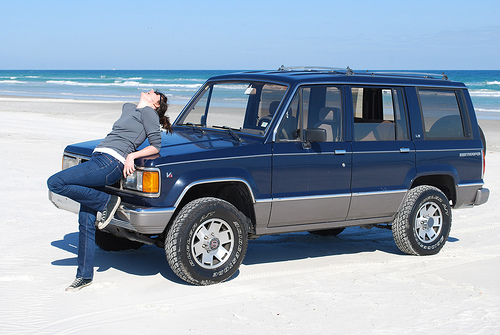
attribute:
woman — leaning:
[43, 87, 176, 298]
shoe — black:
[65, 275, 92, 295]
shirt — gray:
[91, 101, 169, 160]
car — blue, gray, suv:
[52, 65, 490, 284]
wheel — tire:
[164, 197, 251, 285]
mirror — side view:
[298, 129, 328, 146]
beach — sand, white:
[4, 97, 499, 329]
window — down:
[342, 82, 412, 143]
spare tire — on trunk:
[426, 115, 488, 184]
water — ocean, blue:
[3, 70, 500, 121]